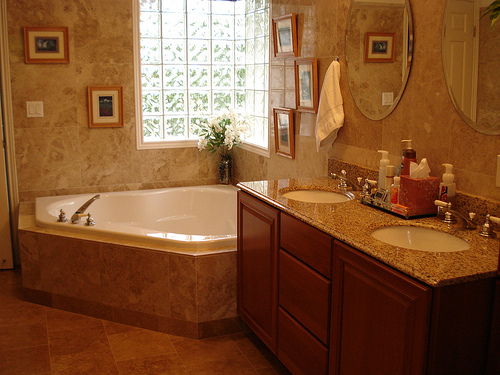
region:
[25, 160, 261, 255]
a white bath tub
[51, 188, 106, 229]
chrome water faucet with knobs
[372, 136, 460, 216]
beauty products in bottles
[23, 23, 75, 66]
a picture frame on the wall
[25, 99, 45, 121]
light switches on the wall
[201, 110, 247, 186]
a vase with white flowers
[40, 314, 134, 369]
brown tiles on the floor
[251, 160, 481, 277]
a dual sink vanity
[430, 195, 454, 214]
a white handled faucet knob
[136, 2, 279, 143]
a glass block corner window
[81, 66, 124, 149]
a picture hanging on a wall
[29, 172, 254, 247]
a large round bathtub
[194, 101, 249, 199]
white flowers in a vase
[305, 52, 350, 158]
a towel hanging on a hook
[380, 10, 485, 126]
two round mirrors hanging on the wall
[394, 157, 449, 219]
a box of tissues on a counter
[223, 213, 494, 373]
a wood bathroom vanity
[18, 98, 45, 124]
a white double light switch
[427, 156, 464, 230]
a plastic bottle of hand soap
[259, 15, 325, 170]
three framed pictures hanging on the wall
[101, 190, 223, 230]
this is a sink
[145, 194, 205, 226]
the sinks is white in color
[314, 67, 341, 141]
this is a towel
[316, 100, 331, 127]
the towel is white in color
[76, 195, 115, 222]
this is a tap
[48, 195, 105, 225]
the tap is metallic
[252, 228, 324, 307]
this is a cupboard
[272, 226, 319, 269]
the cupboard is brown in color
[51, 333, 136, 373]
this is the floor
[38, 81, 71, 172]
this is the wall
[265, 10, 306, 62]
Picture hanging of the wall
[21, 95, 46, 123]
Push in button light switches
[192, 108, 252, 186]
Vase of white flowers in the corner of the tub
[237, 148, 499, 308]
Double Grantite Sink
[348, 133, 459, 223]
Dish of all different bathroom accessories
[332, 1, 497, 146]
Two bathroom mirrors without frames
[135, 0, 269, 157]
Glass Blocks for the bathroom window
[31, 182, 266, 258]
Shiny White Jazzuci Tub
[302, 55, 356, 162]
White towel hanging from a hook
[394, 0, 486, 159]
Reflection of the bathroom door